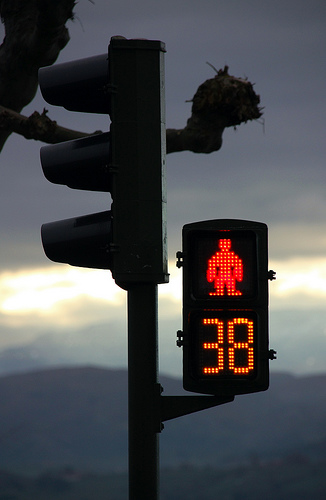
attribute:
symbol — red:
[207, 229, 253, 298]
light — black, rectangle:
[184, 211, 280, 385]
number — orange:
[203, 303, 264, 380]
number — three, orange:
[193, 314, 232, 381]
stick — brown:
[0, 105, 100, 147]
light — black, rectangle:
[28, 41, 171, 289]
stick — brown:
[171, 72, 267, 150]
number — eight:
[228, 319, 260, 374]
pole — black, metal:
[153, 393, 229, 418]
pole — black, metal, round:
[113, 285, 170, 495]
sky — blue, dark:
[11, 50, 310, 262]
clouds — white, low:
[30, 251, 326, 327]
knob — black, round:
[265, 267, 279, 281]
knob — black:
[259, 346, 282, 364]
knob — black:
[174, 248, 190, 258]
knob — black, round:
[174, 259, 191, 271]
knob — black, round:
[175, 325, 187, 338]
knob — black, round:
[178, 339, 184, 347]